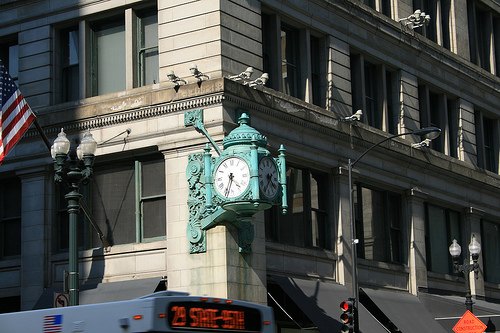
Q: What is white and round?
A: Clock.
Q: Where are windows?
A: On the building.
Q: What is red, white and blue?
A: American flag.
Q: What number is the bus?
A: 29.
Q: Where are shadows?
A: On the building.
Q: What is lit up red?
A: Traffic light.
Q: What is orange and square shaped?
A: Sign.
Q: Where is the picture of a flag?
A: On side of bus.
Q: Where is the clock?
A: On the corner of the building.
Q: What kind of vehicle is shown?
A: A bus.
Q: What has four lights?
A: The street lamp.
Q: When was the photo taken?
A: Daytime.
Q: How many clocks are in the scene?
A: One.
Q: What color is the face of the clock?
A: White.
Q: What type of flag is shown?
A: United States.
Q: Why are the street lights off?
A: It is daytime.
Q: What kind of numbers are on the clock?
A: Roman.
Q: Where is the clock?
A: On the building.